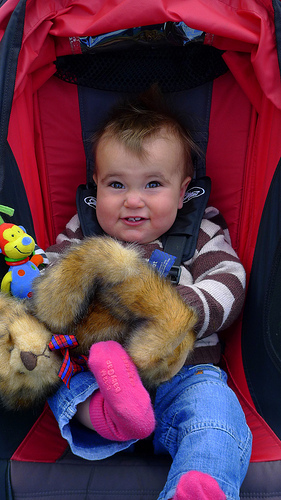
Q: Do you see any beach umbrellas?
A: No, there are no beach umbrellas.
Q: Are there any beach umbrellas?
A: No, there are no beach umbrellas.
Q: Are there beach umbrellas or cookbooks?
A: No, there are no beach umbrellas or cookbooks.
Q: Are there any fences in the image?
A: No, there are no fences.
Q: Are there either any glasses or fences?
A: No, there are no fences or glasses.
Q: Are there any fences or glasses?
A: No, there are no fences or glasses.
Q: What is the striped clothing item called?
A: The clothing item is a shirt.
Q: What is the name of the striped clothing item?
A: The clothing item is a shirt.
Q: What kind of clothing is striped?
A: The clothing is a shirt.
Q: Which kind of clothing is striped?
A: The clothing is a shirt.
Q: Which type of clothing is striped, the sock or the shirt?
A: The shirt is striped.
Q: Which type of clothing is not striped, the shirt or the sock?
A: The sock is not striped.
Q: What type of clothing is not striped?
A: The clothing is a sock.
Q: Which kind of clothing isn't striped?
A: The clothing is a sock.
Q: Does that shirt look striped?
A: Yes, the shirt is striped.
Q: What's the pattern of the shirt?
A: The shirt is striped.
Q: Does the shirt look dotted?
A: No, the shirt is striped.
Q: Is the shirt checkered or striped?
A: The shirt is striped.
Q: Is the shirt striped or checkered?
A: The shirt is striped.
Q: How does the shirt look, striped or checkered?
A: The shirt is striped.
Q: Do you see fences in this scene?
A: No, there are no fences.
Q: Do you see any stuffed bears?
A: Yes, there is a stuffed bear.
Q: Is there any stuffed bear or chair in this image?
A: Yes, there is a stuffed bear.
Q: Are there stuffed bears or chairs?
A: Yes, there is a stuffed bear.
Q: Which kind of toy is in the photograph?
A: The toy is a stuffed bear.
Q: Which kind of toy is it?
A: The toy is a stuffed bear.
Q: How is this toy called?
A: This is a stuffed bear.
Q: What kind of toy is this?
A: This is a stuffed bear.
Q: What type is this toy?
A: This is a stuffed bear.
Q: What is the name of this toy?
A: This is a stuffed bear.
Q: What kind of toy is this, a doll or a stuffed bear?
A: This is a stuffed bear.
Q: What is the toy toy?
A: The toy is a stuffed bear.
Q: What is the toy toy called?
A: The toy is a stuffed bear.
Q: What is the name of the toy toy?
A: The toy is a stuffed bear.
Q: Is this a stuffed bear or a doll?
A: This is a stuffed bear.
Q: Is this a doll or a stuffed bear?
A: This is a stuffed bear.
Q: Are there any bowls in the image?
A: No, there are no bowls.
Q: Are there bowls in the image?
A: No, there are no bowls.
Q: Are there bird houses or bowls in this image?
A: No, there are no bowls or bird houses.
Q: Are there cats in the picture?
A: No, there are no cats.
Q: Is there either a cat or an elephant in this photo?
A: No, there are no cats or elephants.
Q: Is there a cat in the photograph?
A: No, there are no cats.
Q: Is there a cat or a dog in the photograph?
A: No, there are no cats or dogs.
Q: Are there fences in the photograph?
A: No, there are no fences.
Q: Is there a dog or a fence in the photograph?
A: No, there are no fences or dogs.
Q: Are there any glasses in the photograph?
A: No, there are no glasses.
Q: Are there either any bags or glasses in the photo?
A: No, there are no glasses or bags.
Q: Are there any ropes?
A: No, there are no ropes.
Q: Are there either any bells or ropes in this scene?
A: No, there are no ropes or bells.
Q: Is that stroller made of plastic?
A: Yes, the stroller is made of plastic.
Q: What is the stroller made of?
A: The stroller is made of plastic.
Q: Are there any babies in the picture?
A: Yes, there is a baby.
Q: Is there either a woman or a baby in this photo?
A: Yes, there is a baby.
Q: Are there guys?
A: No, there are no guys.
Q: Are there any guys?
A: No, there are no guys.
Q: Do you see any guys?
A: No, there are no guys.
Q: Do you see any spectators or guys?
A: No, there are no guys or spectators.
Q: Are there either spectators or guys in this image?
A: No, there are no guys or spectators.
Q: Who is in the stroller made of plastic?
A: The baby is in the stroller.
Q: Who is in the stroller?
A: The baby is in the stroller.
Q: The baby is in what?
A: The baby is in the stroller.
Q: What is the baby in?
A: The baby is in the stroller.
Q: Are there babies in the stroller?
A: Yes, there is a baby in the stroller.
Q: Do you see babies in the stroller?
A: Yes, there is a baby in the stroller.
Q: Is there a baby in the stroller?
A: Yes, there is a baby in the stroller.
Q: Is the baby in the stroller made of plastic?
A: Yes, the baby is in the stroller.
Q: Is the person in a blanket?
A: No, the baby is in the stroller.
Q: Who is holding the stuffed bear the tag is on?
A: The baby is holding the stuffed bear.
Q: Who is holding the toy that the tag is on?
A: The baby is holding the stuffed bear.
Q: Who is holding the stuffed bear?
A: The baby is holding the stuffed bear.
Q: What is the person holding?
A: The baby is holding the stuffed bear.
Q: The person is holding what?
A: The baby is holding the stuffed bear.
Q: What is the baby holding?
A: The baby is holding the stuffed bear.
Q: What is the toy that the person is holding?
A: The toy is a stuffed bear.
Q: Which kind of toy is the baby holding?
A: The baby is holding the stuffed bear.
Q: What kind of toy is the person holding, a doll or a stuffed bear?
A: The baby is holding a stuffed bear.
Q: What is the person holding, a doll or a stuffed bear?
A: The baby is holding a stuffed bear.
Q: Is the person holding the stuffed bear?
A: Yes, the baby is holding the stuffed bear.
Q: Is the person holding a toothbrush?
A: No, the baby is holding the stuffed bear.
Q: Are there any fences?
A: No, there are no fences.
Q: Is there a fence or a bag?
A: No, there are no fences or bags.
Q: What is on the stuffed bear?
A: The tag is on the stuffed bear.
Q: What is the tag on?
A: The tag is on the stuffed bear.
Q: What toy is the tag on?
A: The tag is on the stuffed bear.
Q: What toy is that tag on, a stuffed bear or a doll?
A: The tag is on a stuffed bear.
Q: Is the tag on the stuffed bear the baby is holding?
A: Yes, the tag is on the stuffed bear.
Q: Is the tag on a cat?
A: No, the tag is on the stuffed bear.